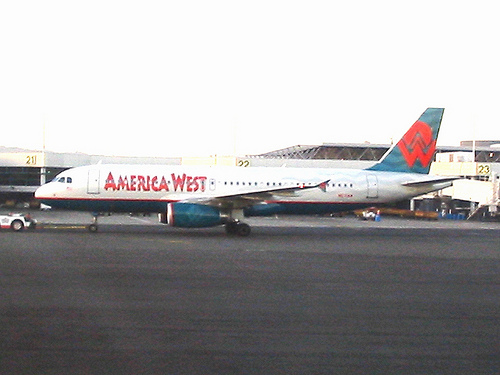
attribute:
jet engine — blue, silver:
[159, 197, 239, 226]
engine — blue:
[167, 202, 229, 227]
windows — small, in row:
[98, 176, 356, 191]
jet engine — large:
[163, 202, 232, 235]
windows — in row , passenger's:
[87, 175, 362, 190]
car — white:
[4, 205, 46, 242]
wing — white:
[177, 177, 342, 207]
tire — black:
[236, 220, 253, 240]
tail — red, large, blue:
[370, 105, 445, 180]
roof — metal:
[237, 137, 499, 167]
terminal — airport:
[4, 136, 496, 231]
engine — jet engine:
[163, 197, 226, 229]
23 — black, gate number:
[478, 164, 489, 173]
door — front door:
[86, 166, 103, 194]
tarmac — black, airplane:
[1, 228, 494, 372]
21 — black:
[23, 155, 35, 166]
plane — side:
[33, 108, 468, 238]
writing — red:
[101, 166, 205, 194]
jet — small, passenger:
[36, 123, 487, 258]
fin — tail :
[404, 171, 464, 196]